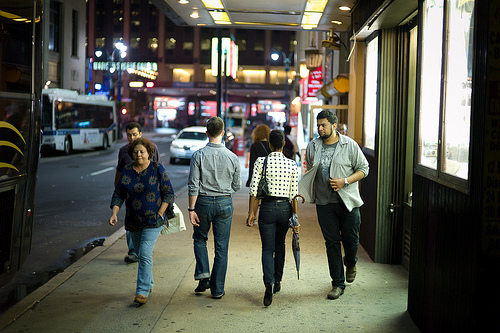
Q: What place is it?
A: It is a sidewalk.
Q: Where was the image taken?
A: It was taken at the sidewalk.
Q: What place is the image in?
A: It is at the sidewalk.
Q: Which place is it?
A: It is a sidewalk.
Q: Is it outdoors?
A: Yes, it is outdoors.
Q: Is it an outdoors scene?
A: Yes, it is outdoors.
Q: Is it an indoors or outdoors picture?
A: It is outdoors.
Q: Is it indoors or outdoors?
A: It is outdoors.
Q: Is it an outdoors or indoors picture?
A: It is outdoors.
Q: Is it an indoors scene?
A: No, it is outdoors.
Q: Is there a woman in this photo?
A: Yes, there is a woman.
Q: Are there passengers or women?
A: Yes, there is a woman.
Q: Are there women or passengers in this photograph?
A: Yes, there is a woman.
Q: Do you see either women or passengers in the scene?
A: Yes, there is a woman.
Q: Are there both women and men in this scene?
A: Yes, there are both a woman and a man.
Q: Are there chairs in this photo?
A: No, there are no chairs.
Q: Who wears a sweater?
A: The woman wears a sweater.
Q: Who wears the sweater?
A: The woman wears a sweater.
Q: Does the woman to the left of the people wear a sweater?
A: Yes, the woman wears a sweater.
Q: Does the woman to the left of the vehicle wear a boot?
A: No, the woman wears a sweater.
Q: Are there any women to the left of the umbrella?
A: Yes, there is a woman to the left of the umbrella.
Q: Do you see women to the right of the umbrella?
A: No, the woman is to the left of the umbrella.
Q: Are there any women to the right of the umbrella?
A: No, the woman is to the left of the umbrella.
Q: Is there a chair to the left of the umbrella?
A: No, there is a woman to the left of the umbrella.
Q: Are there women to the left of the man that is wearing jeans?
A: Yes, there is a woman to the left of the man.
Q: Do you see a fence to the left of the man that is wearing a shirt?
A: No, there is a woman to the left of the man.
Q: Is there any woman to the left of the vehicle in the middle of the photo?
A: Yes, there is a woman to the left of the vehicle.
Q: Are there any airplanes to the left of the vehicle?
A: No, there is a woman to the left of the vehicle.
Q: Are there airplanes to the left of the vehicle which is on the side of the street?
A: No, there is a woman to the left of the vehicle.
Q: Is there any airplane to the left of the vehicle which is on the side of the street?
A: No, there is a woman to the left of the vehicle.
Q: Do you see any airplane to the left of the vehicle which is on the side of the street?
A: No, there is a woman to the left of the vehicle.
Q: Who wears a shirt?
A: The woman wears a shirt.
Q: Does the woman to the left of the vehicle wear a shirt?
A: Yes, the woman wears a shirt.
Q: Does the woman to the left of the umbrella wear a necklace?
A: No, the woman wears a shirt.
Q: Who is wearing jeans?
A: The woman is wearing jeans.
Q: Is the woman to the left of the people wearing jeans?
A: Yes, the woman is wearing jeans.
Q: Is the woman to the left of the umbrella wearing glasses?
A: No, the woman is wearing jeans.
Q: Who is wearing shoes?
A: The woman is wearing shoes.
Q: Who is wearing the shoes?
A: The woman is wearing shoes.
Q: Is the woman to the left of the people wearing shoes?
A: Yes, the woman is wearing shoes.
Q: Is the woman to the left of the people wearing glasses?
A: No, the woman is wearing shoes.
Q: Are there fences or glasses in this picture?
A: No, there are no fences or glasses.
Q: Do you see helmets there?
A: No, there are no helmets.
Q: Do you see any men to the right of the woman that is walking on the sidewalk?
A: Yes, there is a man to the right of the woman.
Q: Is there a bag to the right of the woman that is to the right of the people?
A: No, there is a man to the right of the woman.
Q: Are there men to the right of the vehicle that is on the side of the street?
A: Yes, there is a man to the right of the vehicle.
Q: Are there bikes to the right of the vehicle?
A: No, there is a man to the right of the vehicle.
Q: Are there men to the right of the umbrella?
A: Yes, there is a man to the right of the umbrella.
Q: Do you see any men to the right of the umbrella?
A: Yes, there is a man to the right of the umbrella.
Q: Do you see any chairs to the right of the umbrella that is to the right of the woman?
A: No, there is a man to the right of the umbrella.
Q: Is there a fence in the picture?
A: No, there are no fences.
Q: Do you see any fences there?
A: No, there are no fences.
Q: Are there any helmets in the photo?
A: No, there are no helmets.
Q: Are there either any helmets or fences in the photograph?
A: No, there are no helmets or fences.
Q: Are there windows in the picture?
A: Yes, there is a window.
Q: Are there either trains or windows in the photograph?
A: Yes, there is a window.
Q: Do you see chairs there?
A: No, there are no chairs.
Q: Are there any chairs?
A: No, there are no chairs.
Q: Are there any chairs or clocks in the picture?
A: No, there are no chairs or clocks.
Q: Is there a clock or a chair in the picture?
A: No, there are no chairs or clocks.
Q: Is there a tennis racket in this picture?
A: No, there are no rackets.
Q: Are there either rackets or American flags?
A: No, there are no rackets or American flags.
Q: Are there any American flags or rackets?
A: No, there are no rackets or American flags.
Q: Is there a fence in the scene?
A: No, there are no fences.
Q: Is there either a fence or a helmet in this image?
A: No, there are no fences or helmets.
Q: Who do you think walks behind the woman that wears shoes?
A: The man walks behind the woman.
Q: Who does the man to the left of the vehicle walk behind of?
A: The man walks behind the woman.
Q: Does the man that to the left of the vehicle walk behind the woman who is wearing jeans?
A: Yes, the man walks behind the woman.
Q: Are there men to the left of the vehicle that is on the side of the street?
A: Yes, there is a man to the left of the vehicle.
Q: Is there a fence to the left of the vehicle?
A: No, there is a man to the left of the vehicle.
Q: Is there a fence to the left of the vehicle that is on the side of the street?
A: No, there is a man to the left of the vehicle.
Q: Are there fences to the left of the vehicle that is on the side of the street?
A: No, there is a man to the left of the vehicle.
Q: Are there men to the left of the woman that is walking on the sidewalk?
A: Yes, there is a man to the left of the woman.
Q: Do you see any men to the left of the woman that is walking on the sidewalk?
A: Yes, there is a man to the left of the woman.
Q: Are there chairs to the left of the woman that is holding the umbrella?
A: No, there is a man to the left of the woman.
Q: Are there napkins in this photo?
A: No, there are no napkins.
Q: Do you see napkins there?
A: No, there are no napkins.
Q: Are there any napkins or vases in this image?
A: No, there are no napkins or vases.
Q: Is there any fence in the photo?
A: No, there are no fences.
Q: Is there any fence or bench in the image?
A: No, there are no fences or benches.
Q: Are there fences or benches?
A: No, there are no fences or benches.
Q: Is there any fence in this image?
A: No, there are no fences.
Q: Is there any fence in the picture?
A: No, there are no fences.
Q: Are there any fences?
A: No, there are no fences.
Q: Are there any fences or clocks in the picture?
A: No, there are no fences or clocks.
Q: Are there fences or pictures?
A: No, there are no fences or pictures.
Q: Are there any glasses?
A: No, there are no glasses.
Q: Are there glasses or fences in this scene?
A: No, there are no glasses or fences.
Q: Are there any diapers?
A: No, there are no diapers.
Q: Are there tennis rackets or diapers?
A: No, there are no diapers or tennis rackets.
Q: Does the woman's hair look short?
A: Yes, the hair is short.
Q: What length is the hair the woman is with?
A: The hair is short.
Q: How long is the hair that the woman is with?
A: The hair is short.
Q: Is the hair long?
A: No, the hair is short.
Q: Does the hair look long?
A: No, the hair is short.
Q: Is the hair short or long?
A: The hair is short.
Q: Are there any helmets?
A: No, there are no helmets.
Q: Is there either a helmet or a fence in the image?
A: No, there are no helmets or fences.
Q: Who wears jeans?
A: The man wears jeans.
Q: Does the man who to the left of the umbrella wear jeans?
A: Yes, the man wears jeans.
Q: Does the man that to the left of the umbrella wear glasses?
A: No, the man wears jeans.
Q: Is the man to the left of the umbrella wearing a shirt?
A: Yes, the man is wearing a shirt.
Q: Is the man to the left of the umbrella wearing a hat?
A: No, the man is wearing a shirt.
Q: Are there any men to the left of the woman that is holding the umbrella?
A: Yes, there is a man to the left of the woman.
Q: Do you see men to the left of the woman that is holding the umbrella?
A: Yes, there is a man to the left of the woman.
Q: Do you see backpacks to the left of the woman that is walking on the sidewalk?
A: No, there is a man to the left of the woman.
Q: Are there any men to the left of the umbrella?
A: Yes, there is a man to the left of the umbrella.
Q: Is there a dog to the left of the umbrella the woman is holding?
A: No, there is a man to the left of the umbrella.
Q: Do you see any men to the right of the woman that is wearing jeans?
A: Yes, there is a man to the right of the woman.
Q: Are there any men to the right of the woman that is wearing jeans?
A: Yes, there is a man to the right of the woman.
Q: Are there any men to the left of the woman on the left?
A: No, the man is to the right of the woman.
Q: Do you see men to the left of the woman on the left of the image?
A: No, the man is to the right of the woman.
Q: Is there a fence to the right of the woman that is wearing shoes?
A: No, there is a man to the right of the woman.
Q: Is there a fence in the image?
A: No, there are no fences.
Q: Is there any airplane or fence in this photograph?
A: No, there are no fences or airplanes.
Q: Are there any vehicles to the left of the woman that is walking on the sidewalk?
A: Yes, there is a vehicle to the left of the woman.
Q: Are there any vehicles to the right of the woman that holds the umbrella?
A: No, the vehicle is to the left of the woman.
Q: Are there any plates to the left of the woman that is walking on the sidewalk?
A: No, there is a vehicle to the left of the woman.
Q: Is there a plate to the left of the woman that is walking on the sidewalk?
A: No, there is a vehicle to the left of the woman.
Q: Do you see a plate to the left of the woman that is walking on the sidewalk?
A: No, there is a vehicle to the left of the woman.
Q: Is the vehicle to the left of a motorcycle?
A: No, the vehicle is to the left of the woman.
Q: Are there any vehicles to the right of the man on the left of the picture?
A: Yes, there is a vehicle to the right of the man.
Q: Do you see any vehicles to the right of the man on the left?
A: Yes, there is a vehicle to the right of the man.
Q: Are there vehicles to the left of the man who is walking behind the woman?
A: No, the vehicle is to the right of the man.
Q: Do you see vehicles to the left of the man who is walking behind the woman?
A: No, the vehicle is to the right of the man.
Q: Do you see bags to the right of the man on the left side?
A: No, there is a vehicle to the right of the man.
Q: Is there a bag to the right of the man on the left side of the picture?
A: No, there is a vehicle to the right of the man.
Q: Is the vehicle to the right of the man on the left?
A: Yes, the vehicle is to the right of the man.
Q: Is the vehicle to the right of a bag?
A: No, the vehicle is to the right of the man.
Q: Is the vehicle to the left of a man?
A: No, the vehicle is to the right of a man.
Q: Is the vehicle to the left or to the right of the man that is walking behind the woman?
A: The vehicle is to the right of the man.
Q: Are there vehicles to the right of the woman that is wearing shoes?
A: Yes, there is a vehicle to the right of the woman.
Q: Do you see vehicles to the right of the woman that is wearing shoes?
A: Yes, there is a vehicle to the right of the woman.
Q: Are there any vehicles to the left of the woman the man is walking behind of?
A: No, the vehicle is to the right of the woman.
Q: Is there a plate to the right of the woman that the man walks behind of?
A: No, there is a vehicle to the right of the woman.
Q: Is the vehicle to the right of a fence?
A: No, the vehicle is to the right of a woman.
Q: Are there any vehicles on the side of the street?
A: Yes, there is a vehicle on the side of the street.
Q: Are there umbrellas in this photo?
A: Yes, there is an umbrella.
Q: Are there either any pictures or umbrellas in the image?
A: Yes, there is an umbrella.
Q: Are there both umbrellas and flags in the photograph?
A: No, there is an umbrella but no flags.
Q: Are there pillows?
A: No, there are no pillows.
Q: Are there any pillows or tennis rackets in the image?
A: No, there are no pillows or tennis rackets.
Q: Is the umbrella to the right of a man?
A: No, the umbrella is to the left of a man.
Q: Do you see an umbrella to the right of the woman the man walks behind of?
A: Yes, there is an umbrella to the right of the woman.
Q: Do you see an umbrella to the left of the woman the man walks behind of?
A: No, the umbrella is to the right of the woman.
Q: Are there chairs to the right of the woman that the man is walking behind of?
A: No, there is an umbrella to the right of the woman.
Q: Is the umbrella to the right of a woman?
A: Yes, the umbrella is to the right of a woman.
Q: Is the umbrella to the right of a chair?
A: No, the umbrella is to the right of a woman.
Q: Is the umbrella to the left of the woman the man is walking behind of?
A: No, the umbrella is to the right of the woman.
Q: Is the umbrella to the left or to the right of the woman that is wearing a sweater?
A: The umbrella is to the right of the woman.